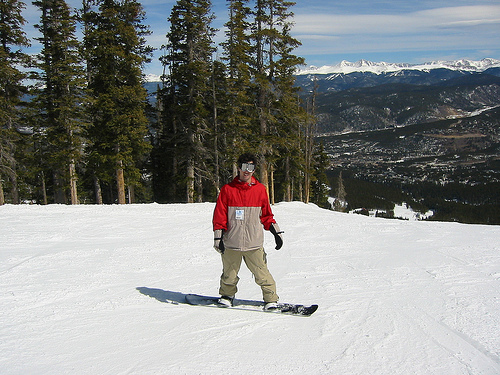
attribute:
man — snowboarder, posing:
[216, 156, 284, 303]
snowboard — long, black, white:
[186, 284, 327, 336]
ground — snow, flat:
[38, 229, 116, 245]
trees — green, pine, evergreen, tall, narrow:
[174, 13, 308, 155]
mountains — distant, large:
[340, 53, 494, 104]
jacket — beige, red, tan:
[217, 177, 275, 252]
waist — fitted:
[225, 221, 263, 231]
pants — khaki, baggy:
[217, 248, 297, 309]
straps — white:
[215, 294, 248, 311]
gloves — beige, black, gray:
[265, 215, 287, 257]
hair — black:
[240, 152, 273, 163]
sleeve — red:
[217, 191, 228, 230]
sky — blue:
[319, 37, 393, 75]